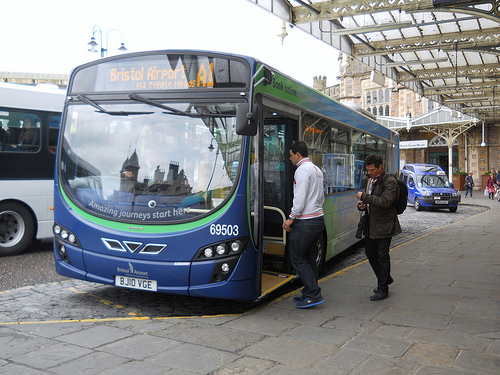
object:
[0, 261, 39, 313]
road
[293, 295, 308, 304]
sneakers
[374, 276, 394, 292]
sneakers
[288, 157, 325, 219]
man sweater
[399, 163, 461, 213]
car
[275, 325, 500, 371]
sidewalk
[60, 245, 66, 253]
headlights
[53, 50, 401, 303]
bus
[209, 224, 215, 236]
number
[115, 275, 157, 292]
license plate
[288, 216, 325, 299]
jeans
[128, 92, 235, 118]
windshield_wipers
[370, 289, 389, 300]
shoes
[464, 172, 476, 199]
man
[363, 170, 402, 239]
jacket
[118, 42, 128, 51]
lamp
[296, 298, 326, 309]
shoe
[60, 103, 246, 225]
window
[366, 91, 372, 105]
window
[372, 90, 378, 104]
window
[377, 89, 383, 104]
window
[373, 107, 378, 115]
window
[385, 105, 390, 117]
window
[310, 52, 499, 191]
building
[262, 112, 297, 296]
doors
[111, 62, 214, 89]
sign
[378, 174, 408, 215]
backpack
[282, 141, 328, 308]
man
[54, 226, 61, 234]
headlight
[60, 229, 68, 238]
headlight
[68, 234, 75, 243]
headlight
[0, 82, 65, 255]
bus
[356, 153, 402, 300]
man